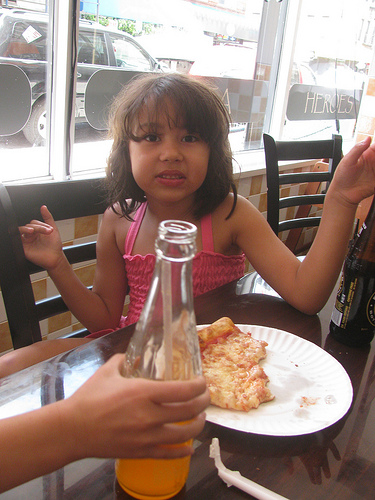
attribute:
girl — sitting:
[71, 72, 281, 300]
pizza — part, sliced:
[207, 327, 259, 411]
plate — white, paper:
[278, 346, 335, 438]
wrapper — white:
[213, 451, 255, 483]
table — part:
[264, 449, 347, 473]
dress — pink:
[190, 256, 248, 285]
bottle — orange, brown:
[140, 219, 192, 493]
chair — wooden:
[258, 134, 313, 246]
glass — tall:
[127, 288, 195, 352]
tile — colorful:
[62, 221, 93, 239]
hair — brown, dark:
[173, 90, 233, 134]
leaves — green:
[115, 21, 134, 34]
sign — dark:
[284, 82, 350, 120]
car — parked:
[7, 18, 110, 119]